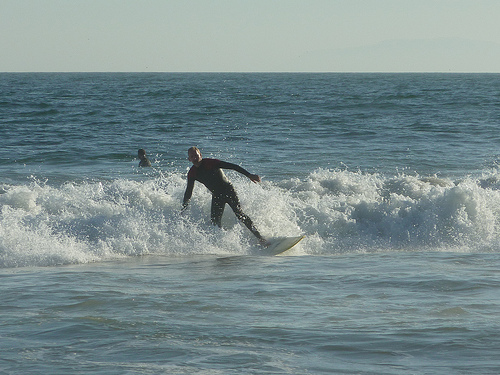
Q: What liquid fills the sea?
A: Water.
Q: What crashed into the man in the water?
A: Waves.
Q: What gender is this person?
A: Male.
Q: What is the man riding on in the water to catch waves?
A: Surfboard.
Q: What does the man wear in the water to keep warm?
A: Wetsuit.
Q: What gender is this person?
A: Male.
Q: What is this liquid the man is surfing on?
A: Water.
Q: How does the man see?
A: Eyes.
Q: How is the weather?
A: Sunny.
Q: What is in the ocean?
A: Man surfing.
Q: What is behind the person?
A: Blue water.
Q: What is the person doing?
A: Man surfing.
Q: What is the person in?
A: White waves.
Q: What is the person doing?
A: Surfing in wave.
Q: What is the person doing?
A: Surfing.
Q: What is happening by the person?
A: Water splashing.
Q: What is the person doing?
A: Surfing.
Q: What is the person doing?
A: Surf in front of wave.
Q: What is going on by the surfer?
A: Water splashing.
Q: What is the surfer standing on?
A: A surfboard.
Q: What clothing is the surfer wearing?
A: A wet suit.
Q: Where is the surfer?
A: In the ocean.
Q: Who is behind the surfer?
A: Another person.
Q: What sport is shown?
A: Surfing.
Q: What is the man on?
A: Surfboard.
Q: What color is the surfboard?
A: White.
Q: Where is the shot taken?
A: Beach.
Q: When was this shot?
A: Daytime.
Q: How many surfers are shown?
A: 1.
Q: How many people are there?
A: 2.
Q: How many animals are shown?
A: 0.